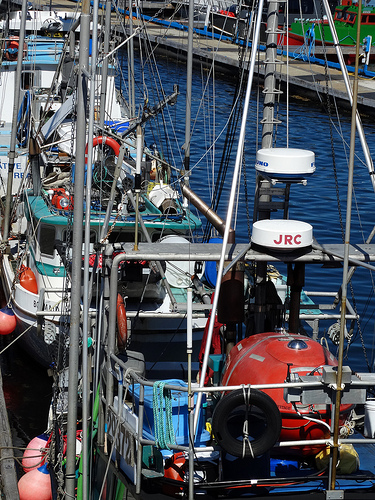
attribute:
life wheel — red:
[88, 134, 129, 175]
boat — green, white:
[9, 126, 231, 356]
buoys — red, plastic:
[20, 433, 53, 498]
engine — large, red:
[215, 334, 339, 457]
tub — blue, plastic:
[131, 374, 200, 436]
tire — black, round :
[210, 389, 282, 460]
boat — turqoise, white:
[3, 150, 219, 337]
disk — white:
[251, 218, 311, 247]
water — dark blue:
[107, 38, 363, 340]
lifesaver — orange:
[84, 135, 120, 168]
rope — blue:
[150, 378, 173, 449]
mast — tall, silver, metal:
[265, 4, 274, 220]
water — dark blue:
[137, 51, 360, 319]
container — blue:
[130, 377, 201, 442]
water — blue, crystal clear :
[105, 37, 361, 375]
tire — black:
[206, 386, 279, 461]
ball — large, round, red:
[210, 329, 345, 460]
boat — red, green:
[275, 3, 360, 68]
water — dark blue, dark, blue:
[112, 48, 362, 326]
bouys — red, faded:
[18, 431, 57, 495]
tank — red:
[17, 262, 39, 295]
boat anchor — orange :
[17, 461, 52, 498]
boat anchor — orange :
[20, 430, 51, 474]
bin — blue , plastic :
[128, 378, 210, 447]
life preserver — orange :
[84, 137, 119, 163]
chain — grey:
[39, 65, 102, 479]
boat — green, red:
[234, 0, 368, 89]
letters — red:
[260, 223, 324, 257]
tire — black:
[195, 380, 304, 478]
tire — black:
[218, 387, 299, 459]